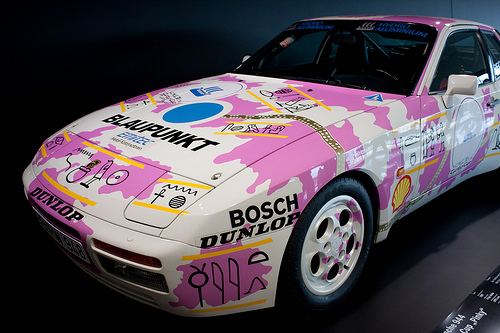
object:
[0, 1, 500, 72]
wall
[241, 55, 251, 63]
car mirror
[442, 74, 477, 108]
car mirror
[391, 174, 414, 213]
logo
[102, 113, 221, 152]
"blaupunkt"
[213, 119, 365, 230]
paint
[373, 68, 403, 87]
steering wheel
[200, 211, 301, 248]
dunlop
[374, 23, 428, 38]
writing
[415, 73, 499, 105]
mirror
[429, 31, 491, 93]
window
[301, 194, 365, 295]
hubcap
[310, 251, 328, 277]
rim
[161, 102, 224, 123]
blue circle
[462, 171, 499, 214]
ground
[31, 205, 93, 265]
plate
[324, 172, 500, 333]
carpet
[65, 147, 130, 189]
symbols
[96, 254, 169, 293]
headlight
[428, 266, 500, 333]
strip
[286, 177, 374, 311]
tire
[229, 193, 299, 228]
bosch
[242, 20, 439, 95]
screen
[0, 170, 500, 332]
floor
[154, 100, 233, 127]
circle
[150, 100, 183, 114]
paint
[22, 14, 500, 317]
automobile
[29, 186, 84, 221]
dunlop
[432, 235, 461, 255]
part